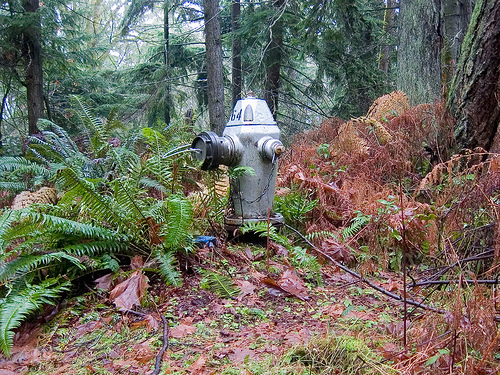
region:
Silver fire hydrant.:
[190, 98, 285, 234]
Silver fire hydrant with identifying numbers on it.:
[189, 98, 289, 253]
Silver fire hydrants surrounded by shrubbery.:
[177, 88, 310, 247]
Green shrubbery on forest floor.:
[11, 111, 186, 296]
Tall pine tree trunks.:
[389, 0, 498, 176]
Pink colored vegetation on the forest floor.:
[300, 130, 457, 287]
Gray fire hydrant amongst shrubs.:
[193, 95, 288, 240]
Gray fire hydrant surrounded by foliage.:
[190, 97, 285, 247]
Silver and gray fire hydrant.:
[186, 91, 286, 241]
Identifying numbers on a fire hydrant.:
[227, 105, 245, 120]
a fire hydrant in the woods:
[187, 85, 291, 246]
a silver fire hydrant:
[187, 92, 291, 247]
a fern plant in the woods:
[17, 147, 199, 297]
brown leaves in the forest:
[298, 90, 484, 272]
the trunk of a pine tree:
[192, 3, 241, 131]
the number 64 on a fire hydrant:
[224, 102, 249, 130]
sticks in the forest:
[290, 232, 498, 311]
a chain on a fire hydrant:
[227, 169, 272, 206]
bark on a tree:
[441, 30, 499, 178]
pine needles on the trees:
[236, 11, 339, 91]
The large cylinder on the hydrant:
[187, 131, 239, 170]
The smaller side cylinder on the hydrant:
[254, 137, 282, 162]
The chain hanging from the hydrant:
[226, 162, 290, 200]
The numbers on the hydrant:
[224, 105, 245, 125]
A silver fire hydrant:
[190, 107, 296, 254]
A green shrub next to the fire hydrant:
[16, 105, 230, 285]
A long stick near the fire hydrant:
[271, 212, 487, 329]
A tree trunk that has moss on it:
[442, 2, 498, 195]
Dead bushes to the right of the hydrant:
[276, 124, 498, 324]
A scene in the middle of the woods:
[14, 13, 498, 367]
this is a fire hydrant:
[187, 52, 298, 273]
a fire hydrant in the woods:
[180, 42, 295, 282]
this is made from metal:
[187, 50, 328, 285]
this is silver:
[150, 60, 336, 260]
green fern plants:
[25, 85, 195, 305]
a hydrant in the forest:
[125, 50, 322, 270]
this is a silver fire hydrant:
[165, 50, 320, 255]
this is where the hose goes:
[180, 115, 220, 180]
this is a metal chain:
[229, 152, 289, 212]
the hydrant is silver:
[184, 61, 296, 253]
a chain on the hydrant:
[226, 145, 295, 214]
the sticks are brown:
[308, 188, 465, 343]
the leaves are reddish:
[300, 92, 427, 232]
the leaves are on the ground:
[194, 243, 330, 356]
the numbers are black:
[215, 102, 247, 126]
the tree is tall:
[175, 0, 231, 126]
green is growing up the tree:
[435, 0, 490, 156]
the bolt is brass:
[270, 140, 292, 157]